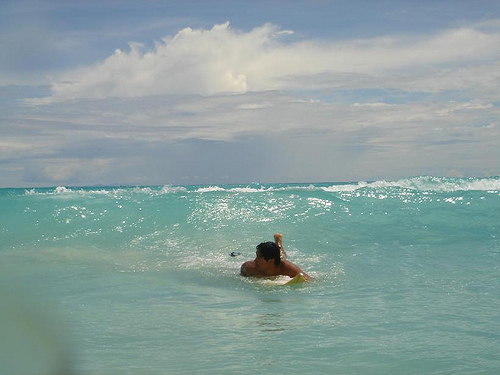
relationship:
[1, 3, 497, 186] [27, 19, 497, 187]
sky has clouds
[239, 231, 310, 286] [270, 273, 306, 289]
man has a board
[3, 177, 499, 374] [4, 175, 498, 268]
ocean has waves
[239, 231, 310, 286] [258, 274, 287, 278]
man has a belly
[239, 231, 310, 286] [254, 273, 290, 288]
man on a board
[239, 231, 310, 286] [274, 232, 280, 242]
man has a foot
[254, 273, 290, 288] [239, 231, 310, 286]
board under man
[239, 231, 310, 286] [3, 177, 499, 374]
man in ocean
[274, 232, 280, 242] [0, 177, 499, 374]
foot out of ocean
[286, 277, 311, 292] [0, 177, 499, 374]
arm in ocean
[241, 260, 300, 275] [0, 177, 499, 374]
shoulder out of ocean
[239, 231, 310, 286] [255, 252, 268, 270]
man has a face